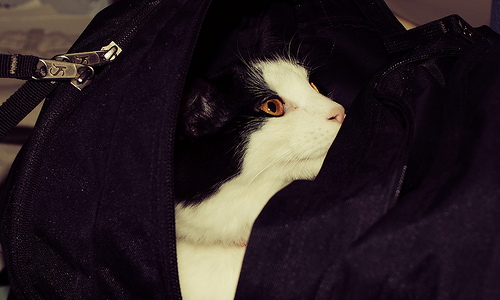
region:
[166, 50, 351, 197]
the cat in the bag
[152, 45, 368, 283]
the cat is black and white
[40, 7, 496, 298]
the bag is black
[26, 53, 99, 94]
the zipper on the bag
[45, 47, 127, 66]
the zipper on the bag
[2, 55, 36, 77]
the pull tab on the zipper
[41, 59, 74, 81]
the logo on the zipper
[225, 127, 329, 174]
whiskers on the cat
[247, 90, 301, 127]
the eye of the cat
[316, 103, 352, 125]
the pink nose of the cat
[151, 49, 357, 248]
cat inside of a bag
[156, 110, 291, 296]
cat inside of a bag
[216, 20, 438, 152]
cat inside of a bag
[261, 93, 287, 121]
cat with orange eyes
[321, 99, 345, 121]
cat with a pink nose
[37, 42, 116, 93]
zipper on a bag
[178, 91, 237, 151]
cat with black hair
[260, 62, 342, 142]
cat with a white face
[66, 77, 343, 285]
cat in a purple bag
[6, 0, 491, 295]
a cat in a bag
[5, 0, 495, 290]
a cat in a purple bag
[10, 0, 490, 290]
a black and white cat in a bag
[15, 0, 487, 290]
a black and white cat in a purple bag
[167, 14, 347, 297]
a black and white cat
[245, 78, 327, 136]
a cats yellow eyes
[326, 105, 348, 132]
a cats pink nose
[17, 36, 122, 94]
a silver zipper on a bag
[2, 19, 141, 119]
a silver zipper on a purple bag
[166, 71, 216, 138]
a black and white cats ear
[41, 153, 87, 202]
lint on bag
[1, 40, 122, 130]
zippers for closing and opening bag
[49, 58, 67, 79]
JS signature, indicating jansport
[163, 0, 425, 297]
pocket of backpack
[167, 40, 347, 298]
black and white cat in backpack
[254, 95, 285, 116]
orange eyes of cat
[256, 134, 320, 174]
white cat whiskers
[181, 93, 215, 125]
inside of cat's ear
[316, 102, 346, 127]
cat nose for breathing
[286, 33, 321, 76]
cat eye lashes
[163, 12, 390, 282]
Cat in a bag.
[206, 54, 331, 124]
Orange eyes on the cat.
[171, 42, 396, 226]
Black and white cat.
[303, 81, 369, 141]
nose on the cat.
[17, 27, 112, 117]
Zipper on the bag.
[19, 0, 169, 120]
silver zipper on the bag.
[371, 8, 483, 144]
Zipper on the bag.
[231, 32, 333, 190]
Whiskers on the cat.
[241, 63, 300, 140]
Orange eye on the cat.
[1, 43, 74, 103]
Tag on the zipper.